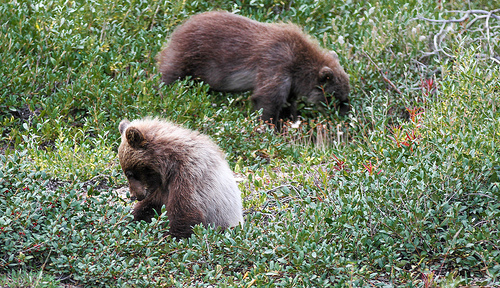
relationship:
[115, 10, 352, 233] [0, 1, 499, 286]
two baby bears on green vegetation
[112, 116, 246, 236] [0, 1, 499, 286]
bear baby on green vegetation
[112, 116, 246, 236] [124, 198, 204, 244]
bear baby on legs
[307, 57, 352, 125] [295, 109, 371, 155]
bears face in plants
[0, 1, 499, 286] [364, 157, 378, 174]
green vegetation has tip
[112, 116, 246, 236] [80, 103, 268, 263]
bear baby over plants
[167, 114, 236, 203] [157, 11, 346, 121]
sunlight on fur is brown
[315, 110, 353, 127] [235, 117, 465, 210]
nose buried in ground